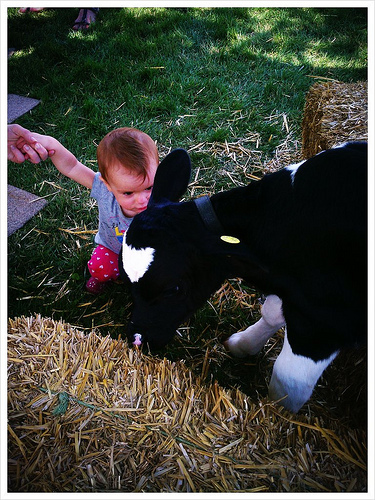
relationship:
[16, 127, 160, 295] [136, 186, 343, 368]
baby playing with calf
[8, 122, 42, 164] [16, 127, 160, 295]
hand holding baby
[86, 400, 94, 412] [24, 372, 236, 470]
piece of rope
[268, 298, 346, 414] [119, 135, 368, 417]
front leg of calf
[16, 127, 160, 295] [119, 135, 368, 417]
baby looking at calf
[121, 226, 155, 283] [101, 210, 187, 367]
patch on face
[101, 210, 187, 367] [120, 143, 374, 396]
face on calf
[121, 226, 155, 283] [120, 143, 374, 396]
patch on calf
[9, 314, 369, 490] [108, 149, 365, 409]
hay bale next to calf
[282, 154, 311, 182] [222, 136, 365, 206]
spot on back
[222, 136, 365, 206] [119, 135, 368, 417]
back of calf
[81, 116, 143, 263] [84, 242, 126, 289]
baby wearing pants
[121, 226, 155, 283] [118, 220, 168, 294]
patch on forehead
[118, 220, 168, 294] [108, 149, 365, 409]
forehead of calf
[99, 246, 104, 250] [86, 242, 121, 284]
heart on pant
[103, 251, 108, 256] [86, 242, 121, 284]
heart on pant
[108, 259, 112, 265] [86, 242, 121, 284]
heart on pant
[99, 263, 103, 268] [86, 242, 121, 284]
heart on pant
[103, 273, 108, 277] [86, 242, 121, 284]
heart on pant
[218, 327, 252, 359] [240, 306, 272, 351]
hoof on calf's leg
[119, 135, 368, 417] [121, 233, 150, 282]
calf has spots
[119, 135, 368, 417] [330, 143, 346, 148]
calf has spots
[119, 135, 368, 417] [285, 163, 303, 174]
calf has spots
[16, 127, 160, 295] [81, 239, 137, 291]
baby wearing shoes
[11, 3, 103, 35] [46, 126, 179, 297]
feet behind child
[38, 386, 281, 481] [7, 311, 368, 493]
rope holding together dry grass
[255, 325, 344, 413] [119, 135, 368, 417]
front leg on calf